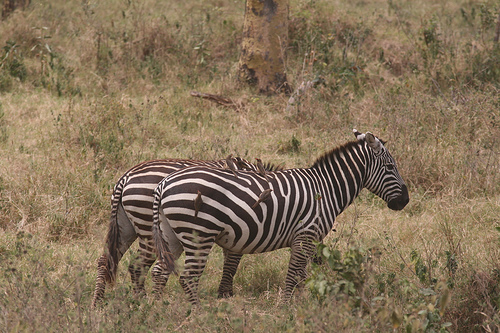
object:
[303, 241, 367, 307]
grass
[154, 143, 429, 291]
zebra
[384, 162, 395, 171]
eye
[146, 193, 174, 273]
tail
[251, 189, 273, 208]
bird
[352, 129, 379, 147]
ear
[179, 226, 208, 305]
legs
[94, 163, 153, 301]
zebra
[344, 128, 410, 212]
head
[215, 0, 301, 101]
tree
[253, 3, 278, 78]
trunk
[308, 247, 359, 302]
weeds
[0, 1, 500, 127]
field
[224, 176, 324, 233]
stripes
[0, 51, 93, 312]
meadow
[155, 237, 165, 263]
tuft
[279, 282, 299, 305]
feet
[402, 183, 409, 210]
nose